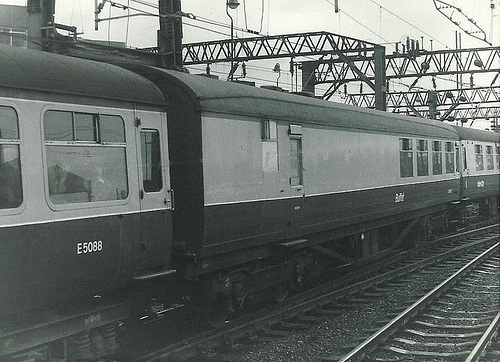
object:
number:
[394, 191, 408, 202]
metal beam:
[393, 105, 498, 123]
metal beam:
[343, 85, 498, 102]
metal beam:
[291, 46, 498, 82]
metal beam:
[177, 29, 377, 63]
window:
[39, 100, 127, 206]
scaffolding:
[137, 30, 498, 132]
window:
[44, 114, 129, 207]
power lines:
[91, 0, 499, 131]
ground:
[421, 113, 451, 160]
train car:
[90, 48, 457, 283]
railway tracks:
[122, 215, 499, 360]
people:
[83, 163, 107, 193]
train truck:
[168, 70, 467, 279]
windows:
[397, 137, 419, 178]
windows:
[469, 141, 499, 173]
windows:
[41, 107, 136, 215]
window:
[400, 138, 415, 176]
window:
[417, 139, 430, 174]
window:
[42, 106, 147, 211]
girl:
[47, 149, 69, 193]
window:
[395, 137, 412, 178]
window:
[0, 104, 27, 215]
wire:
[124, 0, 249, 35]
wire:
[364, 0, 449, 53]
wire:
[324, 0, 407, 53]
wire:
[90, 1, 244, 48]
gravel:
[113, 229, 499, 359]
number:
[72, 239, 104, 254]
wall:
[208, 112, 233, 144]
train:
[0, 45, 498, 362]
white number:
[74, 241, 104, 253]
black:
[47, 243, 70, 260]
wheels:
[0, 189, 494, 356]